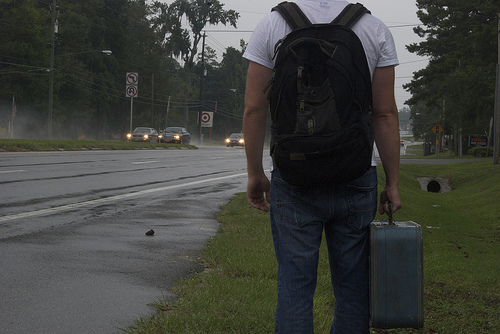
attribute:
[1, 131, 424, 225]
road — wet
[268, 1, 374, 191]
backpack — black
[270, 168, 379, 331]
pair — worn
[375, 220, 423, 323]
suitcase — grey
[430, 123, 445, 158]
traffic light  sign — yellow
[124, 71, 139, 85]
no turn street sign — white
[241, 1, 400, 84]
tee shirt — white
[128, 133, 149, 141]
headlights — on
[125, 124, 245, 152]
cars — moving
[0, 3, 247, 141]
trees — green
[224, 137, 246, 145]
lights — on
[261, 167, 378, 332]
denim jeans — dark blue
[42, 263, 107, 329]
road — muddy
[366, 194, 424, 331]
suitcase — blue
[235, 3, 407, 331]
man — walking, light skinned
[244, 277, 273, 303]
grass — green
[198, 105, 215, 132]
sign — traffic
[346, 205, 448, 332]
suitcase — blue 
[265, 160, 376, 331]
jeans — blue